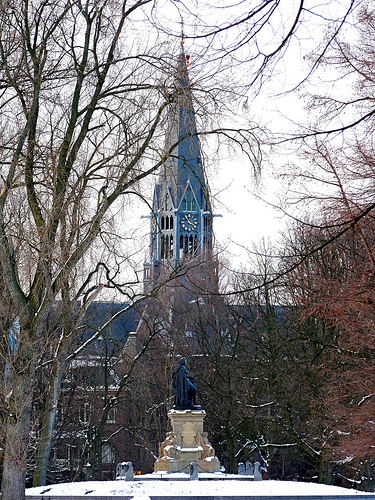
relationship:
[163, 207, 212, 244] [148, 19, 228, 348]
clock on building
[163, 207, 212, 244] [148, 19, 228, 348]
clock in building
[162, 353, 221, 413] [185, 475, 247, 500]
statue in snow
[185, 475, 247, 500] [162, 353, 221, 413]
snow near statue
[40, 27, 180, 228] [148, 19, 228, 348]
tree near building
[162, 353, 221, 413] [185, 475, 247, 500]
statue near snow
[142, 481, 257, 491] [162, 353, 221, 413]
snow fallen on statue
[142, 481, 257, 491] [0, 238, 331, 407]
snow fallen on trees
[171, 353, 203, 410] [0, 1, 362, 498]
statue in town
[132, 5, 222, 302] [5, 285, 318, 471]
steeple on top of church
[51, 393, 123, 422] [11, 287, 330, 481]
windows of church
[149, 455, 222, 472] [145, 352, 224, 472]
base of statue